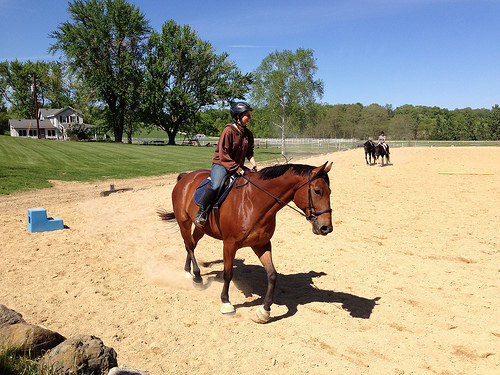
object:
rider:
[194, 102, 259, 225]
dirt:
[363, 170, 446, 201]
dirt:
[37, 245, 87, 271]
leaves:
[161, 19, 176, 37]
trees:
[131, 19, 253, 145]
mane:
[256, 163, 318, 180]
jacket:
[210, 121, 255, 174]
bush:
[471, 108, 499, 141]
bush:
[447, 110, 470, 141]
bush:
[387, 113, 417, 142]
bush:
[414, 116, 437, 140]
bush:
[354, 106, 391, 141]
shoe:
[249, 306, 273, 324]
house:
[8, 104, 113, 142]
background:
[0, 2, 499, 196]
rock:
[33, 333, 118, 373]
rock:
[0, 322, 68, 374]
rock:
[107, 366, 152, 374]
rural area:
[0, 1, 499, 374]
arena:
[0, 146, 499, 374]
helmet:
[230, 100, 253, 117]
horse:
[374, 143, 392, 168]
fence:
[93, 134, 366, 145]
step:
[27, 207, 48, 221]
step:
[47, 213, 65, 231]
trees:
[246, 46, 326, 158]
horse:
[156, 154, 334, 324]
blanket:
[191, 178, 231, 207]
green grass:
[1, 144, 185, 171]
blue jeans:
[210, 164, 228, 190]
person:
[374, 131, 389, 155]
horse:
[363, 139, 380, 166]